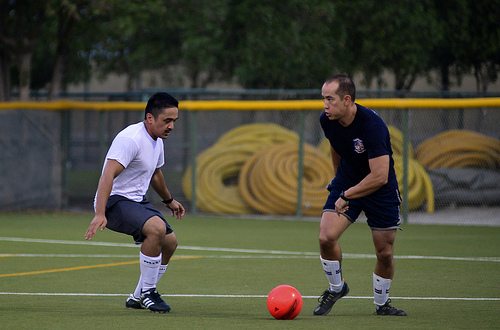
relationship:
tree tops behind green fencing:
[1, 1, 498, 94] [25, 99, 498, 193]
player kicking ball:
[312, 77, 412, 318] [248, 270, 302, 322]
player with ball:
[312, 77, 412, 318] [266, 282, 303, 319]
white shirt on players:
[108, 127, 159, 202] [79, 92, 186, 317]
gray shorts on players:
[102, 190, 179, 245] [79, 92, 186, 317]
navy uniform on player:
[319, 102, 403, 230] [312, 77, 412, 318]